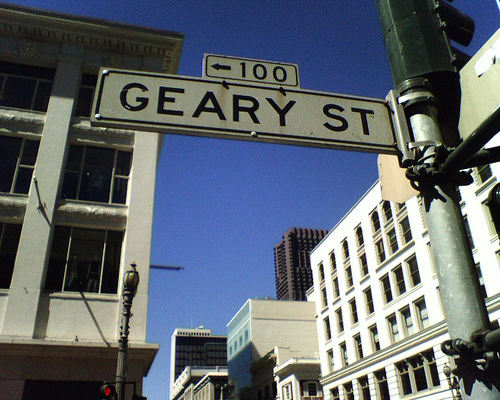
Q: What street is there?
A: Geary.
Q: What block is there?
A: One hundred.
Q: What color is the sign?
A: Black and white.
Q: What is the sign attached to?
A: Pole.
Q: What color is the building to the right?
A: White.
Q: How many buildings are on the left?
A: One.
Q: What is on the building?
A: Windows.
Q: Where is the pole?
A: Street corner.